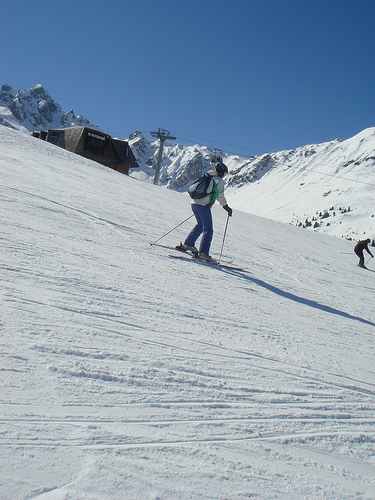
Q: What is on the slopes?
A: Snow.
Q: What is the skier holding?
A: Poles.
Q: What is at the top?
A: Building.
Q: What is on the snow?
A: Ski marks.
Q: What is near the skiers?
A: Lift.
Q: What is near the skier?
A: Shadow.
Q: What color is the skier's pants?
A: Blue.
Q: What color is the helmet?
A: Blue.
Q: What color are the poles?
A: Black.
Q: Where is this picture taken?
A: A ski slope.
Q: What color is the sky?
A: Blue.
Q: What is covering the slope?
A: Snow.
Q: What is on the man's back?
A: A pack.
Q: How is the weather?
A: Clear.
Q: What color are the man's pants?
A: Blue.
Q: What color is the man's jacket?
A: White.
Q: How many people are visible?
A: Two.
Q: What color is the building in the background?
A: Brown.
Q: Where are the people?
A: On a ski slope.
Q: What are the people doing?
A: Skiing.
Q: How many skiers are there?
A: Two.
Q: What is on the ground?
A: Snow.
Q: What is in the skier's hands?
A: Poles.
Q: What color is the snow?
A: White.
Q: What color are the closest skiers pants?
A: Blue.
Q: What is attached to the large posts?
A: Ski lift.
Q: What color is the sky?
A: Blue.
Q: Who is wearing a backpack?
A: The closest man.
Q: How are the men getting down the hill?
A: They are skiing.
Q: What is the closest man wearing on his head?
A: A helmet.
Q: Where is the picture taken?
A: A ski slope.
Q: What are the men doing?
A: Skiing.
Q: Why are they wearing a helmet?
A: To protect their heads.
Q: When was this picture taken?
A: During the day.